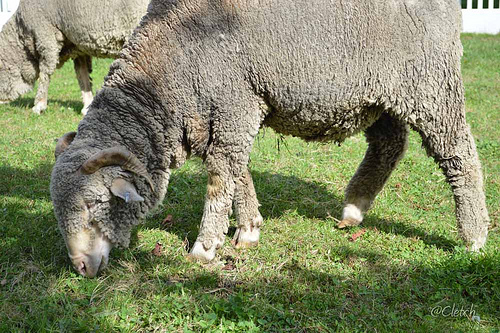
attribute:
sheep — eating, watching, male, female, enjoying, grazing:
[52, 1, 491, 276]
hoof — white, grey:
[188, 228, 263, 261]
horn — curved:
[81, 146, 155, 190]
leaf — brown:
[152, 241, 164, 257]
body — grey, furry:
[179, 2, 463, 136]